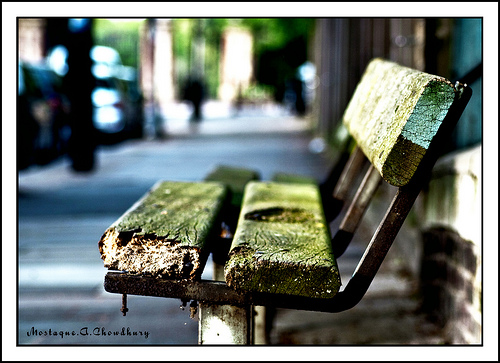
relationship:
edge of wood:
[99, 241, 214, 264] [59, 145, 360, 320]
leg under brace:
[158, 312, 264, 349] [88, 162, 315, 287]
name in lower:
[11, 301, 156, 348] [18, 238, 199, 334]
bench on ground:
[83, 43, 466, 310] [18, 238, 199, 334]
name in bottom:
[11, 301, 156, 348] [40, 293, 196, 340]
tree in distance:
[246, 27, 297, 62] [130, 53, 310, 133]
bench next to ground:
[83, 43, 466, 310] [23, 272, 161, 346]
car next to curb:
[27, 32, 163, 140] [13, 114, 199, 204]